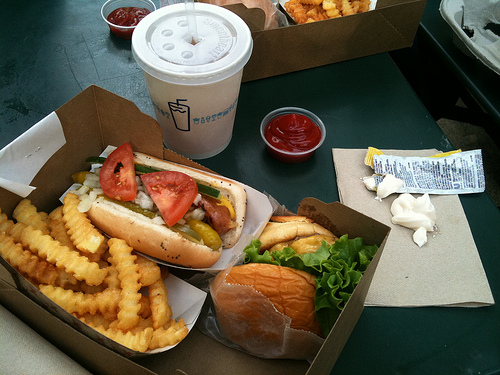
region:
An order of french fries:
[0, 202, 207, 359]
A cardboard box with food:
[21, 82, 392, 373]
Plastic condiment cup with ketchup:
[256, 104, 331, 166]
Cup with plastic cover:
[132, 0, 249, 161]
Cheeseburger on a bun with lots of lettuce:
[210, 215, 350, 360]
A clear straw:
[180, 0, 200, 45]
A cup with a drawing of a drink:
[135, 40, 255, 160]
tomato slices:
[94, 139, 199, 219]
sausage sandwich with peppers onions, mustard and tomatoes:
[61, 137, 251, 272]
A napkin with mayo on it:
[328, 147, 495, 309]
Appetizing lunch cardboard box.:
[2, 151, 389, 366]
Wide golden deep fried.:
[2, 241, 213, 373]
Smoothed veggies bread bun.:
[78, 144, 273, 259]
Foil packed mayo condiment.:
[368, 156, 483, 245]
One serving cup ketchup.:
[243, 96, 340, 171]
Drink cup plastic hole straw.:
[141, 4, 258, 161]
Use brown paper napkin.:
[382, 224, 492, 327]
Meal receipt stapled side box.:
[0, 108, 76, 204]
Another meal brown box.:
[235, 5, 413, 59]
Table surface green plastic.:
[5, 2, 127, 98]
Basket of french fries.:
[19, 199, 169, 346]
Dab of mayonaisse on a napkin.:
[342, 158, 467, 254]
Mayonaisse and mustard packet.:
[345, 138, 460, 190]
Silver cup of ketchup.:
[230, 89, 334, 185]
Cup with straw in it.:
[118, 23, 243, 147]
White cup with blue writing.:
[116, 41, 252, 166]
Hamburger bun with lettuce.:
[218, 218, 366, 328]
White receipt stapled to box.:
[0, 56, 102, 193]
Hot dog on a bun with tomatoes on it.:
[52, 140, 259, 269]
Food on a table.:
[72, 0, 458, 355]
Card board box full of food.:
[0, 86, 387, 372]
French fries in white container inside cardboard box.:
[11, 216, 208, 361]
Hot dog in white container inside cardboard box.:
[78, 143, 254, 276]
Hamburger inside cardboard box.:
[216, 203, 362, 366]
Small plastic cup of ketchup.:
[256, 102, 328, 175]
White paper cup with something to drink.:
[124, 0, 255, 169]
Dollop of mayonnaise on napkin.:
[381, 193, 443, 253]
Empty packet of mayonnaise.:
[352, 139, 489, 201]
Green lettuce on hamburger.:
[304, 231, 380, 335]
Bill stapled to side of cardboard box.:
[5, 106, 74, 197]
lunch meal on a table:
[26, 18, 473, 359]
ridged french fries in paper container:
[10, 236, 190, 353]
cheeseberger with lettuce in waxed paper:
[215, 195, 385, 350]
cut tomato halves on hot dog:
[87, 140, 217, 236]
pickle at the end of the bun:
[180, 201, 226, 251]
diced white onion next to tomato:
[75, 165, 105, 215]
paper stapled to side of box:
[5, 70, 72, 181]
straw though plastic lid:
[135, 6, 260, 86]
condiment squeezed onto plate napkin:
[355, 130, 440, 255]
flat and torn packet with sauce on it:
[348, 142, 484, 195]